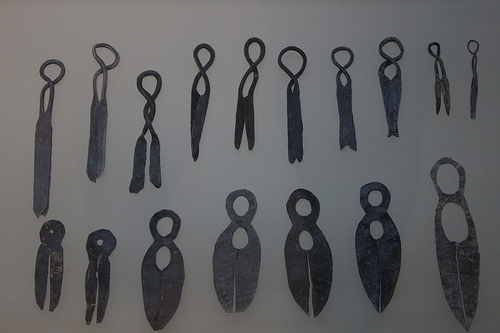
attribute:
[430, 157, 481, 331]
tool — figure-eight shaped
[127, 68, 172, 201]
twisted metal — old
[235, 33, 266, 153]
drawing —  stick person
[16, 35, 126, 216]
scissors — pair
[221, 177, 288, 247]
circle — white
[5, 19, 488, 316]
background — white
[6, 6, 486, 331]
house — bright, lit up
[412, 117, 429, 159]
wall — bright, lit up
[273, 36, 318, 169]
antique tool — scissor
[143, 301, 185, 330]
tip — black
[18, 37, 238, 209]
scissors shears — old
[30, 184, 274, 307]
scissors shears — old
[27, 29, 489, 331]
ancient scissors — collection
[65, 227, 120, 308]
person — Deformed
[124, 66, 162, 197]
scissors — pair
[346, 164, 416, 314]
tool — long, metal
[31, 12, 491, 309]
surface — section, light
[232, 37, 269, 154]
scissors — pair, curvy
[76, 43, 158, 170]
person — poorly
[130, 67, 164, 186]
body —  stick person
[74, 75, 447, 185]
ties — black